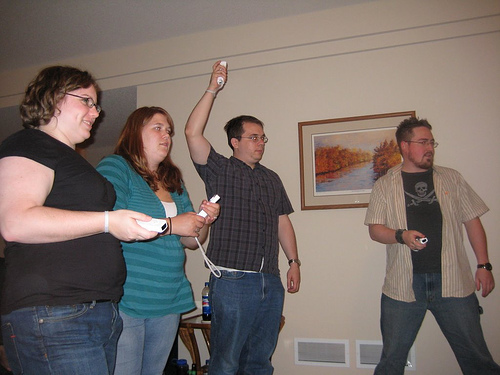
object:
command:
[198, 193, 221, 217]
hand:
[170, 211, 206, 237]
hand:
[198, 199, 222, 225]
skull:
[414, 181, 428, 197]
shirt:
[396, 167, 444, 271]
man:
[362, 116, 499, 375]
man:
[182, 60, 304, 375]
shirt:
[362, 160, 488, 302]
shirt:
[190, 145, 293, 277]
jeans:
[371, 272, 500, 374]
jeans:
[202, 270, 284, 375]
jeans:
[114, 312, 180, 375]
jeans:
[0, 301, 128, 375]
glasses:
[404, 138, 439, 148]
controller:
[132, 212, 169, 233]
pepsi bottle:
[200, 281, 210, 321]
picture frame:
[296, 109, 419, 212]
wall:
[0, 0, 498, 374]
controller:
[414, 235, 430, 246]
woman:
[93, 104, 220, 374]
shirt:
[160, 198, 179, 222]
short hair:
[396, 116, 431, 158]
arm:
[181, 90, 217, 183]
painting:
[297, 109, 417, 211]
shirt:
[1, 126, 127, 307]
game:
[0, 0, 500, 375]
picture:
[297, 109, 419, 211]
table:
[176, 312, 287, 372]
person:
[0, 64, 160, 371]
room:
[0, 0, 482, 372]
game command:
[214, 60, 228, 90]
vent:
[293, 337, 350, 367]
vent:
[354, 339, 415, 369]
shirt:
[92, 151, 198, 313]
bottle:
[201, 281, 212, 321]